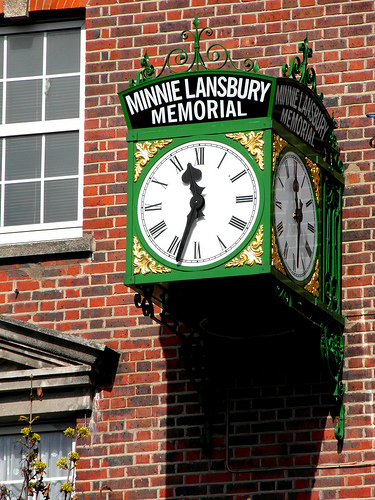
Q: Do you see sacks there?
A: No, there are no sacks.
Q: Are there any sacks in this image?
A: No, there are no sacks.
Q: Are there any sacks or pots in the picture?
A: No, there are no sacks or pots.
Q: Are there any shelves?
A: No, there are no shelves.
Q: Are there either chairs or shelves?
A: No, there are no shelves or chairs.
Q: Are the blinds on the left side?
A: Yes, the blinds are on the left of the image.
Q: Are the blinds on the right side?
A: No, the blinds are on the left of the image.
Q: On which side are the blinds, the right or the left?
A: The blinds are on the left of the image.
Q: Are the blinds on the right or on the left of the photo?
A: The blinds are on the left of the image.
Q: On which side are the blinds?
A: The blinds are on the left of the image.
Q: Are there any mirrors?
A: No, there are no mirrors.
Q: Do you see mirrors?
A: No, there are no mirrors.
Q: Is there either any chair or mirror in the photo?
A: No, there are no mirrors or chairs.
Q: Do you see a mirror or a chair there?
A: No, there are no mirrors or chairs.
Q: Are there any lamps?
A: No, there are no lamps.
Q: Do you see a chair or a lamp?
A: No, there are no lamps or chairs.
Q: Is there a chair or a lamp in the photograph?
A: No, there are no lamps or chairs.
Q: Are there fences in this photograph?
A: No, there are no fences.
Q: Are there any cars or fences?
A: No, there are no fences or cars.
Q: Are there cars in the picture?
A: No, there are no cars.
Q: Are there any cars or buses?
A: No, there are no cars or buses.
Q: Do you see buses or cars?
A: No, there are no cars or buses.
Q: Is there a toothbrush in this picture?
A: No, there are no toothbrushes.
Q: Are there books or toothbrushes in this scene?
A: No, there are no toothbrushes or books.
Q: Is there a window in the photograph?
A: Yes, there is a window.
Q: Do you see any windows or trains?
A: Yes, there is a window.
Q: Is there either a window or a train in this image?
A: Yes, there is a window.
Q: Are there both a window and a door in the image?
A: No, there is a window but no doors.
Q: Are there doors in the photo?
A: No, there are no doors.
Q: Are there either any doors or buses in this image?
A: No, there are no doors or buses.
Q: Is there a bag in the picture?
A: No, there are no bags.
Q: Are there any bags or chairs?
A: No, there are no bags or chairs.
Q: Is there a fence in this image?
A: No, there are no fences.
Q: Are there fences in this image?
A: No, there are no fences.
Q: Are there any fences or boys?
A: No, there are no fences or boys.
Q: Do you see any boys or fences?
A: No, there are no fences or boys.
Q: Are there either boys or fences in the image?
A: No, there are no fences or boys.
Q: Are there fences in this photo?
A: No, there are no fences.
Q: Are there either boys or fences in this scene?
A: No, there are no fences or boys.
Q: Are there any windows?
A: Yes, there is a window.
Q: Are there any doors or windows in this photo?
A: Yes, there is a window.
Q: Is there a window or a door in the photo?
A: Yes, there is a window.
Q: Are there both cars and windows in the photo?
A: No, there is a window but no cars.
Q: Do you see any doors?
A: No, there are no doors.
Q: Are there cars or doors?
A: No, there are no doors or cars.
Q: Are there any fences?
A: No, there are no fences.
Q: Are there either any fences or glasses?
A: No, there are no fences or glasses.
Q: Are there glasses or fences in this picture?
A: No, there are no fences or glasses.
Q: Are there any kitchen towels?
A: No, there are no kitchen towels.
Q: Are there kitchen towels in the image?
A: No, there are no kitchen towels.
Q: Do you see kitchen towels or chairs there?
A: No, there are no kitchen towels or chairs.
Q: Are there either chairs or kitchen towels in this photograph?
A: No, there are no kitchen towels or chairs.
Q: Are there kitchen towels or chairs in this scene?
A: No, there are no kitchen towels or chairs.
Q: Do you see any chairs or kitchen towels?
A: No, there are no kitchen towels or chairs.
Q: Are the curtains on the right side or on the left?
A: The curtains are on the left of the image.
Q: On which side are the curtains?
A: The curtains are on the left of the image.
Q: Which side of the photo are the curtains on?
A: The curtains are on the left of the image.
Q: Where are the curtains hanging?
A: The curtains are hanging in the window.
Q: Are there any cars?
A: No, there are no cars.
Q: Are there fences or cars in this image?
A: No, there are no cars or fences.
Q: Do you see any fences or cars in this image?
A: No, there are no cars or fences.